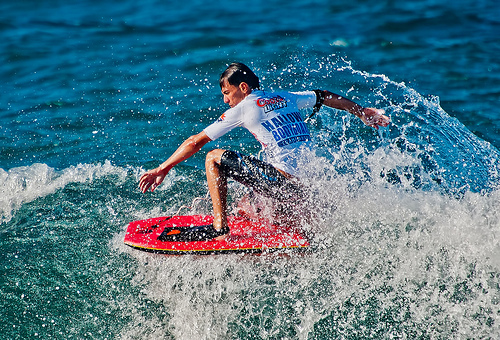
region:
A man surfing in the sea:
[120, 52, 409, 262]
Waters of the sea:
[55, 47, 189, 144]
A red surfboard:
[77, 204, 319, 275]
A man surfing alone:
[115, 49, 405, 279]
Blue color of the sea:
[63, 62, 179, 141]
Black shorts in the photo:
[225, 159, 297, 203]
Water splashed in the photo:
[325, 202, 426, 277]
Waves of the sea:
[69, 259, 279, 335]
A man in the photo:
[127, 39, 394, 274]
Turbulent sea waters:
[66, 7, 176, 48]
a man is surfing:
[35, 23, 413, 309]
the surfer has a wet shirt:
[54, 21, 409, 283]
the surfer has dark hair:
[63, 38, 416, 337]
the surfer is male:
[61, 33, 424, 328]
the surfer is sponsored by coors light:
[22, 14, 353, 256]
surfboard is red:
[88, 84, 373, 276]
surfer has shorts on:
[58, 23, 448, 315]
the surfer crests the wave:
[68, 31, 468, 288]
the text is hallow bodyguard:
[96, 53, 362, 248]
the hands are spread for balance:
[91, 51, 429, 268]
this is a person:
[139, 54, 395, 268]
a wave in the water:
[286, 215, 381, 303]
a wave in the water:
[354, 225, 449, 315]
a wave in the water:
[121, 268, 222, 338]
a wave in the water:
[316, 169, 398, 269]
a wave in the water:
[40, 175, 93, 277]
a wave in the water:
[308, 273, 403, 335]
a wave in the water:
[361, 143, 428, 237]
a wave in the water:
[290, 273, 359, 330]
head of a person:
[213, 55, 263, 111]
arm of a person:
[159, 98, 236, 194]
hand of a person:
[132, 150, 173, 200]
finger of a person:
[132, 167, 152, 197]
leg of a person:
[197, 148, 289, 241]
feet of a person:
[200, 199, 233, 237]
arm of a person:
[301, 73, 373, 126]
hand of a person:
[361, 100, 390, 127]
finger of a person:
[375, 107, 390, 135]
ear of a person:
[232, 82, 251, 98]